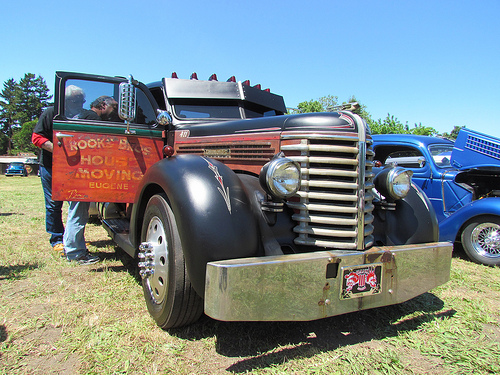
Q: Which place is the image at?
A: It is at the field.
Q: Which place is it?
A: It is a field.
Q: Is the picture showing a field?
A: Yes, it is showing a field.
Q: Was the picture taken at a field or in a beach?
A: It was taken at a field.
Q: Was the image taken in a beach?
A: No, the picture was taken in a field.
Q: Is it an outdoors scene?
A: Yes, it is outdoors.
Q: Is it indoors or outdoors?
A: It is outdoors.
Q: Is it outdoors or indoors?
A: It is outdoors.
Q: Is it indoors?
A: No, it is outdoors.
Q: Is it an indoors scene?
A: No, it is outdoors.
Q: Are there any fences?
A: No, there are no fences.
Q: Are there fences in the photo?
A: No, there are no fences.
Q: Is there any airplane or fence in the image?
A: No, there are no fences or airplanes.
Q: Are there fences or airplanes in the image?
A: No, there are no fences or airplanes.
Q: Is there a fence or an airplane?
A: No, there are no fences or airplanes.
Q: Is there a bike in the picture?
A: No, there are no bikes.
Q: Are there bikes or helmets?
A: No, there are no bikes or helmets.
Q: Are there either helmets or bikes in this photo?
A: No, there are no bikes or helmets.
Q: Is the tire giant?
A: Yes, the tire is giant.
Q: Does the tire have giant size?
A: Yes, the tire is giant.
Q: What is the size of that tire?
A: The tire is giant.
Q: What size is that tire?
A: The tire is giant.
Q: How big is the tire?
A: The tire is giant.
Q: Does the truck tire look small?
A: No, the tire is giant.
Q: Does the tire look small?
A: No, the tire is giant.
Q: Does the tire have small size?
A: No, the tire is giant.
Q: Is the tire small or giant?
A: The tire is giant.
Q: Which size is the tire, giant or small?
A: The tire is giant.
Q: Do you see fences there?
A: No, there are no fences.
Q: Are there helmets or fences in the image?
A: No, there are no fences or helmets.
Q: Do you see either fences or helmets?
A: No, there are no fences or helmets.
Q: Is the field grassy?
A: Yes, the field is grassy.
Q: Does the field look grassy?
A: Yes, the field is grassy.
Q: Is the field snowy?
A: No, the field is grassy.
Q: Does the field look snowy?
A: No, the field is grassy.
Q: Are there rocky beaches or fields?
A: No, there is a field but it is grassy.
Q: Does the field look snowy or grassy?
A: The field is grassy.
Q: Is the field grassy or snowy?
A: The field is grassy.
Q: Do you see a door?
A: Yes, there is a door.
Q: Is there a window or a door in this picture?
A: Yes, there is a door.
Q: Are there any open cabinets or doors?
A: Yes, there is an open door.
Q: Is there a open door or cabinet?
A: Yes, there is an open door.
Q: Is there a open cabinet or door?
A: Yes, there is an open door.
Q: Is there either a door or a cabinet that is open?
A: Yes, the door is open.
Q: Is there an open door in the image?
A: Yes, there is an open door.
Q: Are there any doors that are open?
A: Yes, there is a door that is open.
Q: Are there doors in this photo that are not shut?
A: Yes, there is a open door.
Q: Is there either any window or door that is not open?
A: No, there is a door but it is open.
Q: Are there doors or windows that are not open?
A: No, there is a door but it is open.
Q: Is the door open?
A: Yes, the door is open.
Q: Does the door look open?
A: Yes, the door is open.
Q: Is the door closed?
A: No, the door is open.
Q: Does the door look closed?
A: No, the door is open.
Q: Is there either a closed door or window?
A: No, there is a door but it is open.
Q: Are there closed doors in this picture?
A: No, there is a door but it is open.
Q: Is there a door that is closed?
A: No, there is a door but it is open.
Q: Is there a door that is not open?
A: No, there is a door but it is open.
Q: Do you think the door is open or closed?
A: The door is open.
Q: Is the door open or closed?
A: The door is open.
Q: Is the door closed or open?
A: The door is open.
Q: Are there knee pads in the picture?
A: No, there are no knee pads.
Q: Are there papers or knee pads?
A: No, there are no knee pads or papers.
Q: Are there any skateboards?
A: No, there are no skateboards.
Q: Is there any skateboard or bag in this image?
A: No, there are no skateboards or bags.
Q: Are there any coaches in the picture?
A: No, there are no coaches.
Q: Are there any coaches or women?
A: No, there are no coaches or women.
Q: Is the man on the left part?
A: Yes, the man is on the left of the image.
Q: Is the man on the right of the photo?
A: No, the man is on the left of the image.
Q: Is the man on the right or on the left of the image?
A: The man is on the left of the image.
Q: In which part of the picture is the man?
A: The man is on the left of the image.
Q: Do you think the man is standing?
A: Yes, the man is standing.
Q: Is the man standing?
A: Yes, the man is standing.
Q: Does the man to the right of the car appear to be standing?
A: Yes, the man is standing.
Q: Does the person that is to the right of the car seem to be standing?
A: Yes, the man is standing.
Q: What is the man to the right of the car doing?
A: The man is standing.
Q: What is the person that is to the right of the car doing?
A: The man is standing.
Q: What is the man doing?
A: The man is standing.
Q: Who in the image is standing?
A: The man is standing.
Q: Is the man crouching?
A: No, the man is standing.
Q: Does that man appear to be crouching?
A: No, the man is standing.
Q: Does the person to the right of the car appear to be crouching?
A: No, the man is standing.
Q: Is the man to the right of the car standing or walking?
A: The man is standing.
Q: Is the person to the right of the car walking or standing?
A: The man is standing.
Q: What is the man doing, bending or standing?
A: The man is standing.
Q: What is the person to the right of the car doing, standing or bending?
A: The man is standing.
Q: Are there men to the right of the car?
A: Yes, there is a man to the right of the car.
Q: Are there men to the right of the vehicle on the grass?
A: Yes, there is a man to the right of the car.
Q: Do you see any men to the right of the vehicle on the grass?
A: Yes, there is a man to the right of the car.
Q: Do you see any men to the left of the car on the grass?
A: No, the man is to the right of the car.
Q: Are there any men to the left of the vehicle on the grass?
A: No, the man is to the right of the car.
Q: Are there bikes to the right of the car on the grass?
A: No, there is a man to the right of the car.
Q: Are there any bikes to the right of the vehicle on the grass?
A: No, there is a man to the right of the car.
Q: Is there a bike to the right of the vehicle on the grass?
A: No, there is a man to the right of the car.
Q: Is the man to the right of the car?
A: Yes, the man is to the right of the car.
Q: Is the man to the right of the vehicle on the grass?
A: Yes, the man is to the right of the car.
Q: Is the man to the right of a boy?
A: No, the man is to the right of the car.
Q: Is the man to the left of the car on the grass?
A: No, the man is to the right of the car.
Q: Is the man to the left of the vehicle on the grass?
A: No, the man is to the right of the car.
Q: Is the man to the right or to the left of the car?
A: The man is to the right of the car.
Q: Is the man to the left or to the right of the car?
A: The man is to the right of the car.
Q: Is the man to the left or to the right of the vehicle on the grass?
A: The man is to the right of the car.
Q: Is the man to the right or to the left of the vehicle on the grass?
A: The man is to the right of the car.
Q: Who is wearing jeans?
A: The man is wearing jeans.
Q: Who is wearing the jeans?
A: The man is wearing jeans.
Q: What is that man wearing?
A: The man is wearing jeans.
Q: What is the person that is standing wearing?
A: The man is wearing jeans.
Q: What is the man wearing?
A: The man is wearing jeans.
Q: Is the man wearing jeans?
A: Yes, the man is wearing jeans.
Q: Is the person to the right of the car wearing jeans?
A: Yes, the man is wearing jeans.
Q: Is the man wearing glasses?
A: No, the man is wearing jeans.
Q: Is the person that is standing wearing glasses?
A: No, the man is wearing jeans.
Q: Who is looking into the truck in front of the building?
A: The man is looking into the truck.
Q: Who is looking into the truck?
A: The man is looking into the truck.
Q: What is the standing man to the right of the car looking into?
A: The man is looking into the truck.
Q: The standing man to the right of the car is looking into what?
A: The man is looking into the truck.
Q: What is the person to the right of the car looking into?
A: The man is looking into the truck.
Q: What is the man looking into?
A: The man is looking into the truck.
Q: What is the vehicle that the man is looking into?
A: The vehicle is a truck.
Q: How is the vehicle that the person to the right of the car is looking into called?
A: The vehicle is a truck.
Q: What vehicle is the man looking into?
A: The man is looking into the truck.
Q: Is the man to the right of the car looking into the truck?
A: Yes, the man is looking into the truck.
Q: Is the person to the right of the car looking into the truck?
A: Yes, the man is looking into the truck.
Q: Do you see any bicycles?
A: No, there are no bicycles.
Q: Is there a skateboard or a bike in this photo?
A: No, there are no bikes or skateboards.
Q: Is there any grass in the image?
A: Yes, there is grass.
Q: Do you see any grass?
A: Yes, there is grass.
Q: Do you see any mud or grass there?
A: Yes, there is grass.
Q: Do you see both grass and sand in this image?
A: No, there is grass but no sand.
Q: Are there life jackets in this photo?
A: No, there are no life jackets.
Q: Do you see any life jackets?
A: No, there are no life jackets.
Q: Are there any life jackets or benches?
A: No, there are no life jackets or benches.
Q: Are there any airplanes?
A: No, there are no airplanes.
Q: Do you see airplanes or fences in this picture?
A: No, there are no airplanes or fences.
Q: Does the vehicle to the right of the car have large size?
A: Yes, the vehicle is large.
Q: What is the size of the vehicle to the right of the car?
A: The vehicle is large.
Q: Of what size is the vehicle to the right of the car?
A: The vehicle is large.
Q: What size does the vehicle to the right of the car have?
A: The vehicle has large size.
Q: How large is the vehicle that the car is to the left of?
A: The vehicle is large.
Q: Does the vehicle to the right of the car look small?
A: No, the vehicle is large.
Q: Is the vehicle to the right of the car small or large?
A: The vehicle is large.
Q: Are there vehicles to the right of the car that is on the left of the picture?
A: Yes, there is a vehicle to the right of the car.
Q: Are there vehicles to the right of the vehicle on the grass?
A: Yes, there is a vehicle to the right of the car.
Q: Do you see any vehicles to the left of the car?
A: No, the vehicle is to the right of the car.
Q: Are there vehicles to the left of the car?
A: No, the vehicle is to the right of the car.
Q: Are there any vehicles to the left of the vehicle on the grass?
A: No, the vehicle is to the right of the car.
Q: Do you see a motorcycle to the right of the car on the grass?
A: No, there is a vehicle to the right of the car.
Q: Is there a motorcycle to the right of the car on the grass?
A: No, there is a vehicle to the right of the car.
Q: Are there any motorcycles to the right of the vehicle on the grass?
A: No, there is a vehicle to the right of the car.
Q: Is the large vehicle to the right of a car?
A: Yes, the vehicle is to the right of a car.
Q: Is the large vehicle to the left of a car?
A: No, the vehicle is to the right of a car.